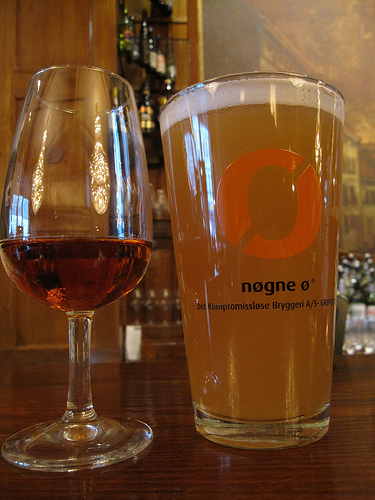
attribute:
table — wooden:
[0, 352, 375, 498]